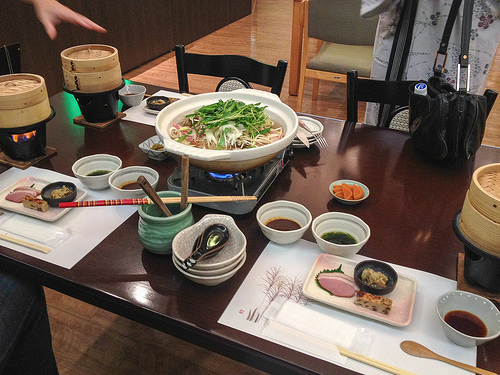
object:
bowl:
[434, 290, 500, 347]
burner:
[166, 141, 293, 215]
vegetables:
[177, 99, 272, 150]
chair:
[174, 44, 288, 98]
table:
[0, 80, 500, 375]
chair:
[347, 70, 419, 132]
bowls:
[172, 213, 247, 286]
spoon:
[181, 223, 231, 270]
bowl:
[255, 200, 313, 245]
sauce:
[266, 219, 299, 232]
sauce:
[321, 231, 356, 245]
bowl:
[312, 211, 371, 258]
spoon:
[399, 339, 500, 375]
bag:
[407, 0, 499, 161]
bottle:
[414, 83, 428, 96]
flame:
[208, 172, 240, 180]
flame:
[10, 129, 37, 142]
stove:
[0, 105, 56, 161]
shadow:
[99, 242, 225, 330]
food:
[168, 99, 288, 150]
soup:
[444, 309, 488, 338]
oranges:
[332, 182, 364, 200]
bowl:
[328, 179, 370, 205]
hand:
[27, 0, 108, 41]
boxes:
[0, 72, 50, 129]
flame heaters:
[60, 79, 124, 123]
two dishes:
[86, 170, 141, 190]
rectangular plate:
[0, 174, 88, 222]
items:
[6, 180, 74, 213]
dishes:
[301, 253, 416, 328]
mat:
[217, 241, 477, 375]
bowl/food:
[154, 88, 299, 174]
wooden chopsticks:
[58, 196, 258, 208]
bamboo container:
[60, 44, 123, 93]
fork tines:
[296, 120, 329, 150]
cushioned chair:
[295, 0, 380, 111]